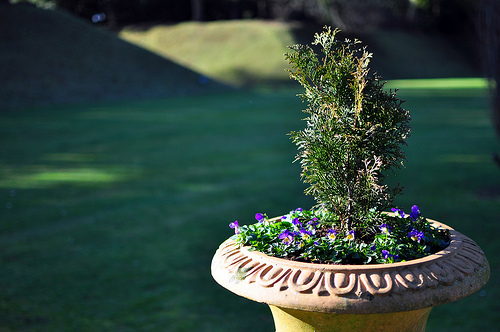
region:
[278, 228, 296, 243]
pansy in the pot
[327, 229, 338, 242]
pansy in the pot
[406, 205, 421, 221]
pansy in the pot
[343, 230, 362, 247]
pansy in the pot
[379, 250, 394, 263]
pansy in the pot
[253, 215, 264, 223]
pansy in the pot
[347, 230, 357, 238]
pansy in the pot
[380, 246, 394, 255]
pansy in the pot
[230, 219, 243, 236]
pansy in the pot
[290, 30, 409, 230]
A green shrub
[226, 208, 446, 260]
Purple flowers in a pot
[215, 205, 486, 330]
A fancy flower pot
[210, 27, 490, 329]
A green plant in a fancy pot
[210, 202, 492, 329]
A plant pot with a fancy pattern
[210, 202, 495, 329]
A fancy planter with a scalloped edge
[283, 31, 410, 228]
A single green plant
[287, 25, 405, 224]
A lone green plant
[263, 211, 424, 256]
Potting soil in a planter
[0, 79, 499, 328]
a freshly mowed lawn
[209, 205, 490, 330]
Yellow and light brown planter.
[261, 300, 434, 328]
Yellow base of a very close planter.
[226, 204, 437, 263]
Purple small flowers in the base of a planter.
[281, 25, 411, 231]
A small green bush in a planter.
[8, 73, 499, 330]
All the green vibrant grass.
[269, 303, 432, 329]
Yellow concrete base of a planter.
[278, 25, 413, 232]
A green bush that is small in the planter.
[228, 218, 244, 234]
Left most purple flower in the pot.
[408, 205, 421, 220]
Top right most purple flower in the planter.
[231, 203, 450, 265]
All the little purple flowers.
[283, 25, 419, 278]
plant with the pot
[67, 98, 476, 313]
green lawn with pot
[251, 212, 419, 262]
blue color flowers with the plant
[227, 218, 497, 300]
top of the pot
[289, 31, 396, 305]
a plant planting in the pot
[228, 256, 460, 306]
design on the top of the pot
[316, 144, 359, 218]
leaves in the plant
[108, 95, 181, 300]
shadow of the trees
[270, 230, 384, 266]
small blue color flowers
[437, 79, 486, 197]
green color grass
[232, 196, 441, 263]
The purple flowers in the plant holder.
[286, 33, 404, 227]
The pine tree in the pot holder.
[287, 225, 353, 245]
The yellow centers of the purple flowers.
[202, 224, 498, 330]
The pot holder the flowers are in.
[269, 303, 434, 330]
The bottom base of the pot holder.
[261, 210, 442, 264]
The center area of the pot holder.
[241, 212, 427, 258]
The green leaves of the purple flowers.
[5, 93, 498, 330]
The green grass area.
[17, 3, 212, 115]
The slanted hill on the left.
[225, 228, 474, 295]
The design on the top of the plant holder.